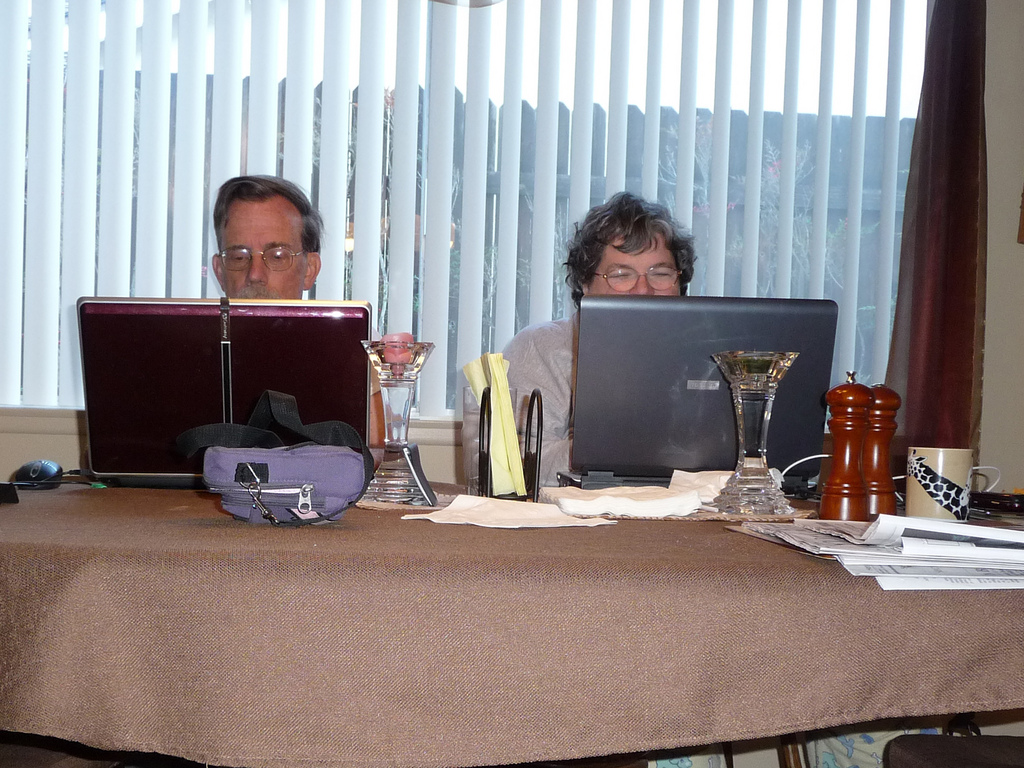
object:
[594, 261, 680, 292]
eyeglasses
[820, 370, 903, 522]
shaker shaker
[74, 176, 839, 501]
people computers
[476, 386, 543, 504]
holder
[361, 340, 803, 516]
holder holder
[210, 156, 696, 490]
man woman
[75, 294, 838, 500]
computers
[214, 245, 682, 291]
glasses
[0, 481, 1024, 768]
cloth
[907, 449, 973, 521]
giraffe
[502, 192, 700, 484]
person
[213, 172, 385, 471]
man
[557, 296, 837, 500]
computer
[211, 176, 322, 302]
person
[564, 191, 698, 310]
person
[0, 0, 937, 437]
blinds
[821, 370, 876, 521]
shaker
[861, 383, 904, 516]
shaker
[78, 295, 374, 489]
computer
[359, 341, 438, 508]
candlestick holder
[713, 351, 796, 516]
candlestick holder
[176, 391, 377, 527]
pouch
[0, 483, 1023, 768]
table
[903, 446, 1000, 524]
mug